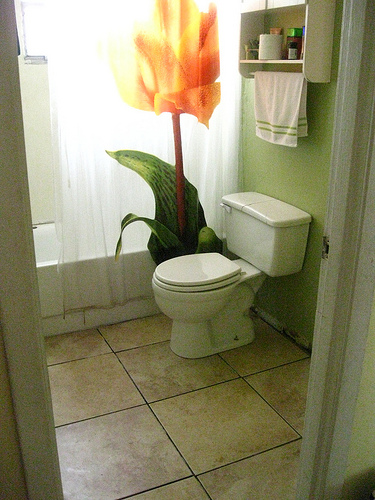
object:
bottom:
[252, 309, 311, 354]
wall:
[315, 102, 327, 198]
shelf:
[238, 0, 336, 86]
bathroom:
[0, 0, 349, 500]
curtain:
[24, 0, 235, 311]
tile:
[147, 376, 301, 477]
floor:
[35, 353, 284, 499]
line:
[256, 120, 296, 137]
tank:
[219, 191, 312, 279]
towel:
[253, 69, 308, 148]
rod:
[239, 63, 308, 81]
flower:
[104, 0, 221, 264]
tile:
[112, 340, 240, 408]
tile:
[220, 315, 309, 377]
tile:
[44, 350, 146, 431]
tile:
[55, 404, 196, 500]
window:
[12, 0, 243, 264]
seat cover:
[155, 251, 242, 286]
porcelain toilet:
[151, 191, 312, 360]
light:
[44, 1, 81, 50]